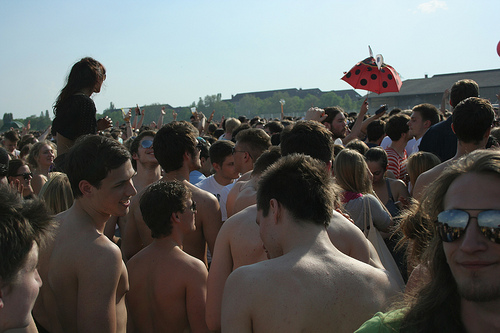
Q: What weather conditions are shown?
A: It is clear.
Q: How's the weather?
A: It is clear.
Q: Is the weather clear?
A: Yes, it is clear.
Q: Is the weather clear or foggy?
A: It is clear.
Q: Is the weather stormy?
A: No, it is clear.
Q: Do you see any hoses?
A: No, there are no hoses.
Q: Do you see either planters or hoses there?
A: No, there are no hoses or planters.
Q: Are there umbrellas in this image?
A: Yes, there is an umbrella.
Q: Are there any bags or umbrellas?
A: Yes, there is an umbrella.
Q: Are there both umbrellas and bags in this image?
A: Yes, there are both an umbrella and a bag.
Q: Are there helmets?
A: No, there are no helmets.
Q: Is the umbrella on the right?
A: Yes, the umbrella is on the right of the image.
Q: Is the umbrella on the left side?
A: No, the umbrella is on the right of the image.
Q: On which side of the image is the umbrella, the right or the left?
A: The umbrella is on the right of the image.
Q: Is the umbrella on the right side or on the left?
A: The umbrella is on the right of the image.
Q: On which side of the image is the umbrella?
A: The umbrella is on the right of the image.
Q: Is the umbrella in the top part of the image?
A: Yes, the umbrella is in the top of the image.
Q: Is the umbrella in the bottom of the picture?
A: No, the umbrella is in the top of the image.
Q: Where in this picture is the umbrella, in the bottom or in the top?
A: The umbrella is in the top of the image.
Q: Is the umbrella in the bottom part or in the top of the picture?
A: The umbrella is in the top of the image.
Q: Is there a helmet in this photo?
A: No, there are no helmets.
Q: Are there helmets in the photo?
A: No, there are no helmets.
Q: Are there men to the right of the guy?
A: Yes, there is a man to the right of the guy.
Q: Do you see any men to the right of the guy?
A: Yes, there is a man to the right of the guy.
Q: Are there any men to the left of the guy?
A: No, the man is to the right of the guy.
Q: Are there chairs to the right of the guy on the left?
A: No, there is a man to the right of the guy.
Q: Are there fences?
A: No, there are no fences.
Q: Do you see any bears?
A: No, there are no bears.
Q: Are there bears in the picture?
A: No, there are no bears.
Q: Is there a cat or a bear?
A: No, there are no bears or cats.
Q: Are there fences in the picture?
A: No, there are no fences.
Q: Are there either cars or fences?
A: No, there are no fences or cars.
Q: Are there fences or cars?
A: No, there are no fences or cars.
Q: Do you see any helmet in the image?
A: No, there are no helmets.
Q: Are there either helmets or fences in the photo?
A: No, there are no helmets or fences.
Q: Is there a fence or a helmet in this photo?
A: No, there are no helmets or fences.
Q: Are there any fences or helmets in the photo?
A: No, there are no helmets or fences.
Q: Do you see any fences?
A: No, there are no fences.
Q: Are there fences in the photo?
A: No, there are no fences.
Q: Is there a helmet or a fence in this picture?
A: No, there are no fences or helmets.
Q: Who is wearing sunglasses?
A: The man is wearing sunglasses.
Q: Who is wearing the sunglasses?
A: The man is wearing sunglasses.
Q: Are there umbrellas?
A: Yes, there is an umbrella.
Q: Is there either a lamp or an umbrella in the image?
A: Yes, there is an umbrella.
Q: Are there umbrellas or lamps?
A: Yes, there is an umbrella.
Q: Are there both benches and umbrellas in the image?
A: No, there is an umbrella but no benches.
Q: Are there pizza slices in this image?
A: No, there are no pizza slices.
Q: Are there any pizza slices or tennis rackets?
A: No, there are no pizza slices or tennis rackets.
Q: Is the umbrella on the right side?
A: Yes, the umbrella is on the right of the image.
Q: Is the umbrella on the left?
A: No, the umbrella is on the right of the image.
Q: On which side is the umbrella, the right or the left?
A: The umbrella is on the right of the image.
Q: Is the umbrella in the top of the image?
A: Yes, the umbrella is in the top of the image.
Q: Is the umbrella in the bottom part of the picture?
A: No, the umbrella is in the top of the image.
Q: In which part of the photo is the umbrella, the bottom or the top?
A: The umbrella is in the top of the image.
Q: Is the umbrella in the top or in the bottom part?
A: The umbrella is in the top of the image.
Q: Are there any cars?
A: No, there are no cars.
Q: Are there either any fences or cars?
A: No, there are no cars or fences.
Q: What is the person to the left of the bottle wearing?
A: The person is wearing a shirt.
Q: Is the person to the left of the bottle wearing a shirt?
A: Yes, the person is wearing a shirt.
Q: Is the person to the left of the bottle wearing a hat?
A: No, the person is wearing a shirt.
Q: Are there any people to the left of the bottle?
A: Yes, there is a person to the left of the bottle.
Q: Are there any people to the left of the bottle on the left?
A: Yes, there is a person to the left of the bottle.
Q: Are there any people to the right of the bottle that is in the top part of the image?
A: No, the person is to the left of the bottle.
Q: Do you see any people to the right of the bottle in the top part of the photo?
A: No, the person is to the left of the bottle.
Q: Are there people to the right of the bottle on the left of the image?
A: No, the person is to the left of the bottle.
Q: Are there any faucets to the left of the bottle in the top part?
A: No, there is a person to the left of the bottle.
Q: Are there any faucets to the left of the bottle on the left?
A: No, there is a person to the left of the bottle.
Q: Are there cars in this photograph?
A: No, there are no cars.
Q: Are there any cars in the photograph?
A: No, there are no cars.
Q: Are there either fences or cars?
A: No, there are no cars or fences.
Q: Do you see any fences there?
A: No, there are no fences.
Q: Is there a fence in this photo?
A: No, there are no fences.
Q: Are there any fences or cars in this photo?
A: No, there are no fences or cars.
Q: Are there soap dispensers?
A: No, there are no soap dispensers.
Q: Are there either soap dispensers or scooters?
A: No, there are no soap dispensers or scooters.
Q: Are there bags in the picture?
A: Yes, there is a bag.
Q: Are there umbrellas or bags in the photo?
A: Yes, there is a bag.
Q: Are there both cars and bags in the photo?
A: No, there is a bag but no cars.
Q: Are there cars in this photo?
A: No, there are no cars.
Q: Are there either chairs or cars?
A: No, there are no cars or chairs.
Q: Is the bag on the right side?
A: Yes, the bag is on the right of the image.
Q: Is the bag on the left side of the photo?
A: No, the bag is on the right of the image.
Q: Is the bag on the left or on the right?
A: The bag is on the right of the image.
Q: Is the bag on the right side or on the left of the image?
A: The bag is on the right of the image.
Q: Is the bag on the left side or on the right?
A: The bag is on the right of the image.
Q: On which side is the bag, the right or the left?
A: The bag is on the right of the image.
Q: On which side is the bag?
A: The bag is on the right of the image.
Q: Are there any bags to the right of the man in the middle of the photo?
A: Yes, there is a bag to the right of the man.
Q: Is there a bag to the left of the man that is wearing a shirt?
A: No, the bag is to the right of the man.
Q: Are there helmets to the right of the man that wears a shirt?
A: No, there is a bag to the right of the man.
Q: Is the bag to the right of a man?
A: Yes, the bag is to the right of a man.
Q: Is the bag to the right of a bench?
A: No, the bag is to the right of a man.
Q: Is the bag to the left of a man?
A: No, the bag is to the right of a man.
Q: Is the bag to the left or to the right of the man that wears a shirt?
A: The bag is to the right of the man.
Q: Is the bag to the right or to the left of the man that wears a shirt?
A: The bag is to the right of the man.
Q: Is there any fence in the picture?
A: No, there are no fences.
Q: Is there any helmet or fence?
A: No, there are no fences or helmets.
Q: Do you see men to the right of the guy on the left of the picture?
A: Yes, there is a man to the right of the guy.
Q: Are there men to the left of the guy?
A: No, the man is to the right of the guy.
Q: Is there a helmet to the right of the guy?
A: No, there is a man to the right of the guy.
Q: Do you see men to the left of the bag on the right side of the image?
A: Yes, there is a man to the left of the bag.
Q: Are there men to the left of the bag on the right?
A: Yes, there is a man to the left of the bag.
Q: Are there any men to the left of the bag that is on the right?
A: Yes, there is a man to the left of the bag.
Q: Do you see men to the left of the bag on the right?
A: Yes, there is a man to the left of the bag.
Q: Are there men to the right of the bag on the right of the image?
A: No, the man is to the left of the bag.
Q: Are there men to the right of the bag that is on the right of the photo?
A: No, the man is to the left of the bag.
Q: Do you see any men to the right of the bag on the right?
A: No, the man is to the left of the bag.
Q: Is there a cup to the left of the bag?
A: No, there is a man to the left of the bag.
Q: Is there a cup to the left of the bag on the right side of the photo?
A: No, there is a man to the left of the bag.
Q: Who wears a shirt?
A: The man wears a shirt.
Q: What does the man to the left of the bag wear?
A: The man wears a shirt.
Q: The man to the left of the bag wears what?
A: The man wears a shirt.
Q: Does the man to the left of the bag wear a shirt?
A: Yes, the man wears a shirt.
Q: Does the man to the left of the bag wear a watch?
A: No, the man wears a shirt.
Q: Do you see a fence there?
A: No, there are no fences.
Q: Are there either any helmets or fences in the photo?
A: No, there are no fences or helmets.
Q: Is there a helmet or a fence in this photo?
A: No, there are no fences or helmets.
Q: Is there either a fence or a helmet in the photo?
A: No, there are no fences or helmets.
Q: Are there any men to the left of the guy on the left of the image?
A: No, the man is to the right of the guy.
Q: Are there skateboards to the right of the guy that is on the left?
A: No, there is a man to the right of the guy.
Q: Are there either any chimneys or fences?
A: No, there are no fences or chimneys.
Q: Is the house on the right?
A: Yes, the house is on the right of the image.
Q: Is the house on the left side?
A: No, the house is on the right of the image.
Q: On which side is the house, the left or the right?
A: The house is on the right of the image.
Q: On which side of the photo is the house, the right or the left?
A: The house is on the right of the image.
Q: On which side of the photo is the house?
A: The house is on the right of the image.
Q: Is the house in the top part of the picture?
A: Yes, the house is in the top of the image.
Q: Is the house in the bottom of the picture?
A: No, the house is in the top of the image.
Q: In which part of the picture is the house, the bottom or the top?
A: The house is in the top of the image.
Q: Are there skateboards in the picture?
A: No, there are no skateboards.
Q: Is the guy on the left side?
A: Yes, the guy is on the left of the image.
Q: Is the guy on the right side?
A: No, the guy is on the left of the image.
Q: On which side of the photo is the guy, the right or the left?
A: The guy is on the left of the image.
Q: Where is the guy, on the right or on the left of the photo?
A: The guy is on the left of the image.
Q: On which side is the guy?
A: The guy is on the left of the image.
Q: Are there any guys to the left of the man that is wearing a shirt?
A: Yes, there is a guy to the left of the man.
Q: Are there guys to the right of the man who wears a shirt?
A: No, the guy is to the left of the man.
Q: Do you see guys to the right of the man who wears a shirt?
A: No, the guy is to the left of the man.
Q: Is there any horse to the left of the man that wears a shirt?
A: No, there is a guy to the left of the man.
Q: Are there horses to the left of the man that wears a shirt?
A: No, there is a guy to the left of the man.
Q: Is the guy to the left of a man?
A: Yes, the guy is to the left of a man.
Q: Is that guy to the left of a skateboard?
A: No, the guy is to the left of a man.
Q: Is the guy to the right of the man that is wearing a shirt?
A: No, the guy is to the left of the man.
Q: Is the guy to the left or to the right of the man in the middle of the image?
A: The guy is to the left of the man.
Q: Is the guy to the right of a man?
A: No, the guy is to the left of a man.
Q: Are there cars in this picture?
A: No, there are no cars.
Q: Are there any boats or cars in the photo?
A: No, there are no cars or boats.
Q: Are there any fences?
A: No, there are no fences.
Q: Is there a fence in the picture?
A: No, there are no fences.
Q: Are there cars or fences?
A: No, there are no fences or cars.